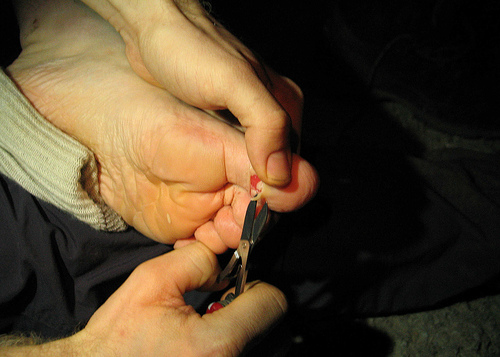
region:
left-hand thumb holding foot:
[245, 88, 294, 183]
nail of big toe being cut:
[252, 175, 266, 201]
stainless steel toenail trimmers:
[212, 199, 270, 300]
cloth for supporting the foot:
[0, 74, 125, 231]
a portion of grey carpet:
[363, 299, 498, 354]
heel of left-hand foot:
[100, 92, 181, 236]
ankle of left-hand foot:
[14, 8, 106, 59]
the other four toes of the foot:
[172, 197, 252, 249]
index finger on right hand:
[211, 282, 297, 353]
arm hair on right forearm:
[0, 325, 77, 355]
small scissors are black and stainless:
[228, 195, 275, 283]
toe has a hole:
[226, 141, 303, 200]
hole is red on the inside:
[246, 173, 279, 186]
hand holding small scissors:
[150, 257, 281, 308]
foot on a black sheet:
[320, 182, 370, 283]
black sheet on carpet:
[397, 317, 435, 335]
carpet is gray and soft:
[433, 332, 475, 350]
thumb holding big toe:
[223, 92, 286, 162]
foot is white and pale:
[20, 36, 50, 61]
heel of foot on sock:
[29, 126, 78, 178]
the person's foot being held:
[15, 55, 318, 263]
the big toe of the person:
[235, 141, 321, 211]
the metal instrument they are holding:
[217, 193, 285, 306]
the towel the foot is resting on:
[3, 75, 130, 230]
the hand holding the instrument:
[91, 258, 298, 355]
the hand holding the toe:
[127, 26, 309, 173]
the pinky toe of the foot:
[198, 225, 227, 252]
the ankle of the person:
[27, 15, 115, 55]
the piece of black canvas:
[5, 182, 204, 330]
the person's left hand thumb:
[246, 103, 303, 178]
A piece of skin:
[255, 192, 262, 199]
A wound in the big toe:
[251, 174, 256, 184]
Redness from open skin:
[251, 177, 258, 182]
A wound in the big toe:
[253, 177, 257, 186]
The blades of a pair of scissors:
[245, 218, 258, 234]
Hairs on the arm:
[6, 335, 30, 352]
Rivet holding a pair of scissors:
[239, 242, 247, 249]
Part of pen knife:
[208, 303, 219, 310]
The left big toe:
[280, 186, 306, 199]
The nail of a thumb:
[270, 158, 285, 178]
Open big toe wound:
[247, 170, 264, 205]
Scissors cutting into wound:
[245, 188, 270, 241]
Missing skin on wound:
[246, 169, 262, 212]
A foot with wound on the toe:
[42, 67, 314, 254]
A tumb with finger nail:
[252, 110, 292, 192]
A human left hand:
[120, 21, 331, 179]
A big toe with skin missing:
[224, 132, 318, 214]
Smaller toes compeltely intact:
[175, 200, 256, 266]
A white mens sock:
[6, 99, 128, 233]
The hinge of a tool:
[235, 234, 257, 259]